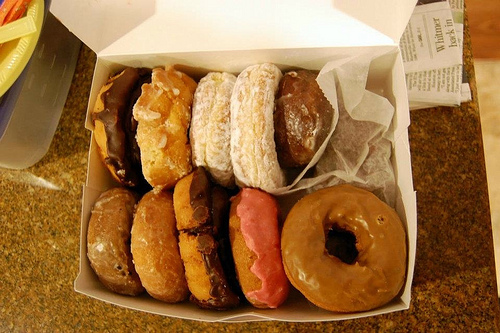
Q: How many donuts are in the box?
A: 10.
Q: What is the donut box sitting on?
A: Counter.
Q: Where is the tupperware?
A: Left of the box.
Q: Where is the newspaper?
A: Under the box.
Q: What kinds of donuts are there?
A: Assorted.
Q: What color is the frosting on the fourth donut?
A: Pink.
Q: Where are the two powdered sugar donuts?
A: In the top row.